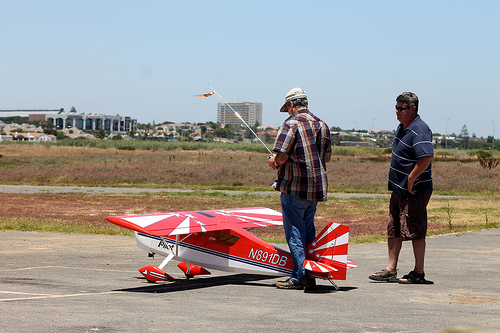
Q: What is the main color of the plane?
A: Red.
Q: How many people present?
A: 2.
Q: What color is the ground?
A: Gray.